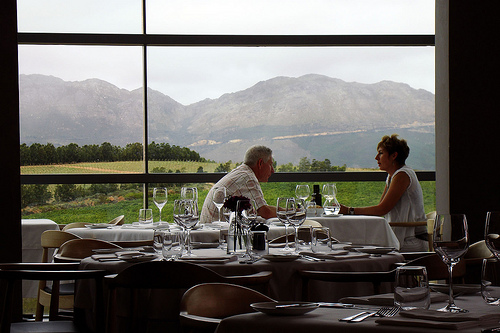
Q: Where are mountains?
A: In the distance.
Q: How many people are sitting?
A: Two.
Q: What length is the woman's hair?
A: Short.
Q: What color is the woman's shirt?
A: White.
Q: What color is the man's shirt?
A: White.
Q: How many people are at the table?
A: 2.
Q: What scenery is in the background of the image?
A: Mountains.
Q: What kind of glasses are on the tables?
A: Wine glasses.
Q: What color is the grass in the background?
A: Green.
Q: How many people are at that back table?
A: Two.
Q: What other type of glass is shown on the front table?
A: Water.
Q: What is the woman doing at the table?
A: Sitting.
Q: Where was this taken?
A: Restaurant.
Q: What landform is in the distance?
A: Mountains.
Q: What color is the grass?
A: Green.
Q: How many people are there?
A: 2.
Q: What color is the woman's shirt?
A: White.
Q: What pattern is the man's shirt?
A: Plaid.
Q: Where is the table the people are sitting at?
A: In front of the window.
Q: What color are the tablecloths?
A: White.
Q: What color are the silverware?
A: Silver.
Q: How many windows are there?
A: 1.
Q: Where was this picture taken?
A: In a restaurant.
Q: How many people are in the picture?
A: Two.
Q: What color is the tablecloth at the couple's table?
A: White.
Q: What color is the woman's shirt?
A: White.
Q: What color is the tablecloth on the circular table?
A: Brown.